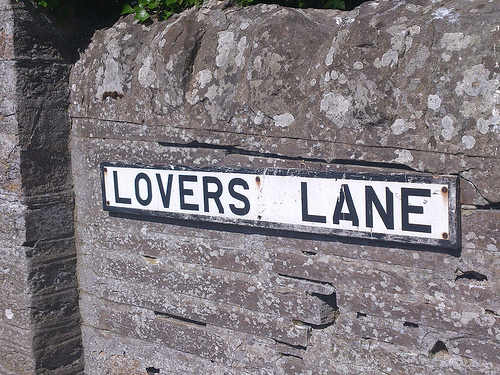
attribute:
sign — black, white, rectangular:
[99, 155, 460, 253]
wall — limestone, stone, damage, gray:
[79, 17, 488, 358]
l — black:
[109, 167, 135, 205]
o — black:
[133, 170, 155, 208]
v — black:
[153, 172, 177, 210]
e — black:
[176, 172, 202, 212]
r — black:
[199, 174, 228, 217]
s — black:
[225, 174, 251, 217]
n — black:
[364, 184, 397, 232]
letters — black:
[112, 170, 252, 214]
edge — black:
[103, 157, 139, 172]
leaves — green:
[107, 0, 287, 16]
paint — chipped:
[231, 215, 285, 226]